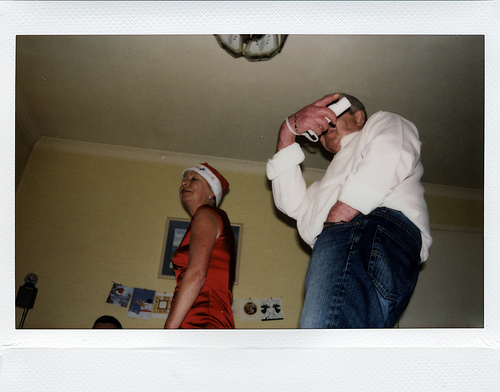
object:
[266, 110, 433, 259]
shirt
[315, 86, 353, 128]
game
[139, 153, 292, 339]
people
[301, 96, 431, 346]
people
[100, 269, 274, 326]
pictures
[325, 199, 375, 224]
hand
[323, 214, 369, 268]
pocket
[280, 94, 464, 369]
man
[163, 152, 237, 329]
santa outfit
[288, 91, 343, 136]
remote control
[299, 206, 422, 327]
jeans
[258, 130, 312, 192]
cuff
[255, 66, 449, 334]
man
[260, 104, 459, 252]
shirt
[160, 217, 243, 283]
picture frame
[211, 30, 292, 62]
light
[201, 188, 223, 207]
earring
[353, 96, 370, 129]
ear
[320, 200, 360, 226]
hand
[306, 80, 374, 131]
phone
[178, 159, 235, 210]
santa hat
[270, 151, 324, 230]
sleeve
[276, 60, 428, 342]
man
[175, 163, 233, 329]
woman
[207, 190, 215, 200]
earring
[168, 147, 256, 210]
head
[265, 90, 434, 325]
man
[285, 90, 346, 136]
hand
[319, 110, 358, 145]
face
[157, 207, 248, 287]
picture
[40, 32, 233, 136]
ceiling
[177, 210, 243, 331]
red dress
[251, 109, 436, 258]
white shirt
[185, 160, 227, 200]
hat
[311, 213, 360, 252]
man's pocket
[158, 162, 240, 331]
woman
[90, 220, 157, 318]
wall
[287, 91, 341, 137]
man's hand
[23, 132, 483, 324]
wall